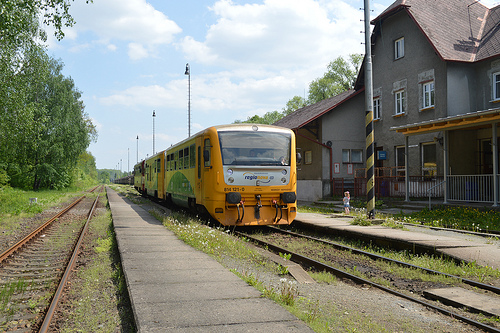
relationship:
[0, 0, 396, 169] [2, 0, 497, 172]
cloud in sky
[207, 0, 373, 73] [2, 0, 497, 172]
cloud in sky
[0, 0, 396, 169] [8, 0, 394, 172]
cloud in sky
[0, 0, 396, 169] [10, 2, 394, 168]
cloud in blue sky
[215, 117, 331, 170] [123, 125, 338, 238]
window on train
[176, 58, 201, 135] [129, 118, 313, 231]
pole over train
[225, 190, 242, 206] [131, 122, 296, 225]
bumper on train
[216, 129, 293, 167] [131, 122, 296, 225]
window on train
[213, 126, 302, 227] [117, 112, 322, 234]
front of train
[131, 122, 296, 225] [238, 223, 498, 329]
train on track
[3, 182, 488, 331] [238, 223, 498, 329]
rocks between track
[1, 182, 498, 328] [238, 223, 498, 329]
grass between track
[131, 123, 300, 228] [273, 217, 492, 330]
train on tracks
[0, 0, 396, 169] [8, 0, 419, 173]
cloud in blue sky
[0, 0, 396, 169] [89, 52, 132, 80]
cloud in sky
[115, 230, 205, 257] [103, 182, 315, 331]
section of sidewalk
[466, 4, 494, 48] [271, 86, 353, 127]
part of roof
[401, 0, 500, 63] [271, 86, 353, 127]
part of roof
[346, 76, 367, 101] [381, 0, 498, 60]
part of roof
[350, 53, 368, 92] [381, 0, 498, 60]
part of roof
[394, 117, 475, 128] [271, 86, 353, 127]
part of roof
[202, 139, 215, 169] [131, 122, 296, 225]
window of train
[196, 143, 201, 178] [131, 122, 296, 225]
window of train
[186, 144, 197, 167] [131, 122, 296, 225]
window of train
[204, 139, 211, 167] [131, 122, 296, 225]
window of train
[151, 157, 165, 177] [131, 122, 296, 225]
window of train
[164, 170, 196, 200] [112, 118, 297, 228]
illustration painted on side of train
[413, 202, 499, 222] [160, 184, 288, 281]
yellow flowers in bed of grass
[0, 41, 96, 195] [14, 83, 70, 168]
tree covered in green leaves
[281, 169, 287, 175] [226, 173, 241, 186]
headlight of train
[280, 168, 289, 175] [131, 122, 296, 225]
headlight of train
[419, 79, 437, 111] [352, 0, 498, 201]
window of building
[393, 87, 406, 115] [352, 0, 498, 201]
window of building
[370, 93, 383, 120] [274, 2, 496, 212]
window of building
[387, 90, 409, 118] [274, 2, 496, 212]
window of building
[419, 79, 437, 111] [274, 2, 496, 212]
window of building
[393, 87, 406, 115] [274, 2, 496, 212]
window of building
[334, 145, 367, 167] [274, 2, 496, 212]
window of building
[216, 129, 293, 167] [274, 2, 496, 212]
window of building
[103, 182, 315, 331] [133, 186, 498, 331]
sidewalk by tracks